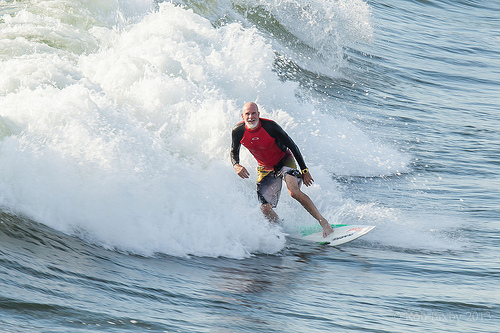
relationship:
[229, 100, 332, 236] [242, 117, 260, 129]
man has beard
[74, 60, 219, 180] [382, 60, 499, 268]
spray of water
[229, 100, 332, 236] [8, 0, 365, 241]
man surfing wave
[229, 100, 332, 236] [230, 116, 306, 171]
man wearing shirt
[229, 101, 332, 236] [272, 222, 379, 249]
man on surfboard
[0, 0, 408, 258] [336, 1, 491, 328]
wave in ocean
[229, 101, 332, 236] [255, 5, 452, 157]
man in ocean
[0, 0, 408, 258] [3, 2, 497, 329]
wave in ocean